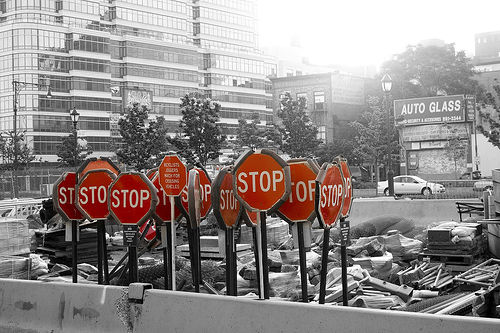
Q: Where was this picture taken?
A: A junk yard.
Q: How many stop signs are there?
A: 15.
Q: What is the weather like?
A: Cloudy.